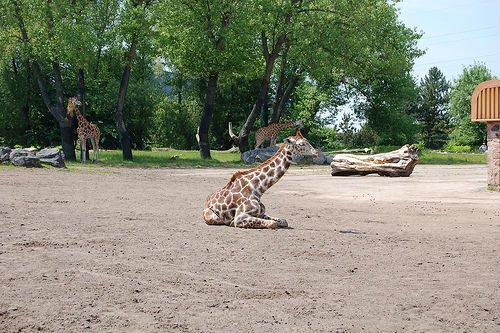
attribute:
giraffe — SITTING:
[200, 122, 320, 229]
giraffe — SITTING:
[62, 90, 102, 167]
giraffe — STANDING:
[251, 112, 299, 155]